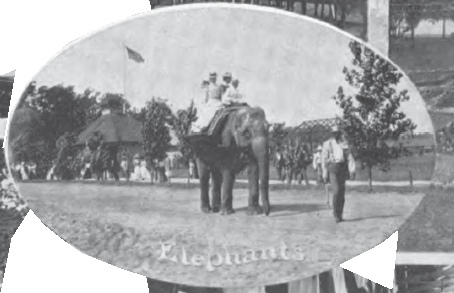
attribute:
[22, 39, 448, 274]
photo — oval, black, white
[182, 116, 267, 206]
elephant — walking on road, on photo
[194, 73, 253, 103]
people — walking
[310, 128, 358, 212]
man — walking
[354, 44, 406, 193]
tree — in background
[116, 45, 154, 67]
flag — on pole, waving, fluttering, american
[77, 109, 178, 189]
building — in background, distant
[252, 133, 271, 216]
trunk — hanging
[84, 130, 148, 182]
cottage — white, in background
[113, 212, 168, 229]
grass — flat, cut